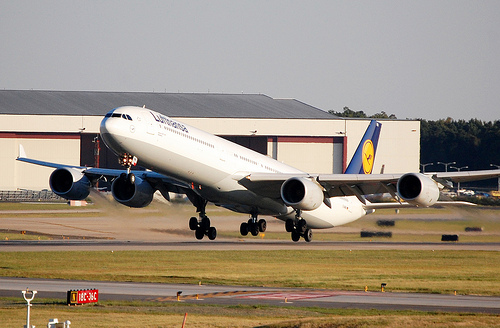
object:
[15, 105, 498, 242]
airplane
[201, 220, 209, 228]
wheel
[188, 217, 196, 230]
wheel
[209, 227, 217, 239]
wheel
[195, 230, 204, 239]
wheel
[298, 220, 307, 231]
wheel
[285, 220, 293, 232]
wheel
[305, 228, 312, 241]
wheel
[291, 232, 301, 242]
wheel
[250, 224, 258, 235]
wheel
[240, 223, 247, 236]
wheel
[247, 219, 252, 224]
wheel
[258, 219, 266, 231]
wheel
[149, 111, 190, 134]
writing